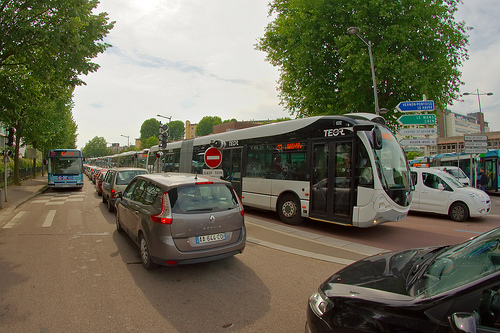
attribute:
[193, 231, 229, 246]
plate — black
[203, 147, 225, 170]
sign — red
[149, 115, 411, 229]
bus — white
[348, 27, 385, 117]
pole — gray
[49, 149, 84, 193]
bus — blue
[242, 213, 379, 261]
cement — gray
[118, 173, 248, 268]
car — gray, brown, silver, compact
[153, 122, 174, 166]
light — double sided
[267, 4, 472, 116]
tree — green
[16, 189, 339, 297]
road — gray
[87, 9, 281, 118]
sky — cloudy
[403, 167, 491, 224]
car — white